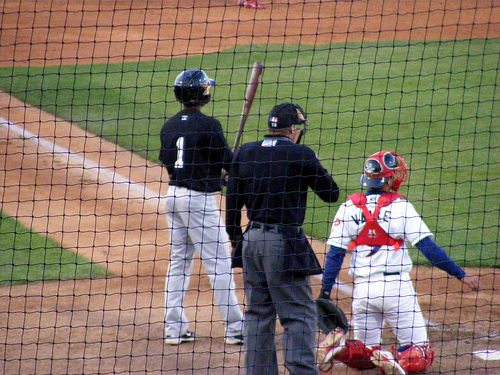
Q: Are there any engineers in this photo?
A: No, there are no engineers.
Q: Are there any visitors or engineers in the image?
A: No, there are no engineers or visitors.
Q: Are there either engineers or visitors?
A: No, there are no engineers or visitors.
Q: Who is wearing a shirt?
A: The man is wearing a shirt.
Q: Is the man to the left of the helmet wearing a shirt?
A: Yes, the man is wearing a shirt.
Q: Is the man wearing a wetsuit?
A: No, the man is wearing a shirt.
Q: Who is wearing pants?
A: The man is wearing pants.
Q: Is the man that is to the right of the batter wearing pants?
A: Yes, the man is wearing pants.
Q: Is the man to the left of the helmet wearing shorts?
A: No, the man is wearing pants.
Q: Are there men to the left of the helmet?
A: Yes, there is a man to the left of the helmet.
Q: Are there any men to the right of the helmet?
A: No, the man is to the left of the helmet.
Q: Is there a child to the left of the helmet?
A: No, there is a man to the left of the helmet.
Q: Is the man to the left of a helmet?
A: Yes, the man is to the left of a helmet.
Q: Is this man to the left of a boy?
A: No, the man is to the left of a helmet.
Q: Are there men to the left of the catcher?
A: Yes, there is a man to the left of the catcher.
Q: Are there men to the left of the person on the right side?
A: Yes, there is a man to the left of the catcher.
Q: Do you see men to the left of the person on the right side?
A: Yes, there is a man to the left of the catcher.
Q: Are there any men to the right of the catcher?
A: No, the man is to the left of the catcher.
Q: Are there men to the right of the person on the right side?
A: No, the man is to the left of the catcher.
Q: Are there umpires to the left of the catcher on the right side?
A: No, there is a man to the left of the catcher.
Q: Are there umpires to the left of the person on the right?
A: No, there is a man to the left of the catcher.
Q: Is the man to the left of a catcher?
A: Yes, the man is to the left of a catcher.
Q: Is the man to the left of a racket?
A: No, the man is to the left of a catcher.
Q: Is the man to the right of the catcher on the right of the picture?
A: No, the man is to the left of the catcher.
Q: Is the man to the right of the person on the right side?
A: No, the man is to the left of the catcher.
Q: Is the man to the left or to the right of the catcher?
A: The man is to the left of the catcher.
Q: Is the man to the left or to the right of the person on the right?
A: The man is to the left of the catcher.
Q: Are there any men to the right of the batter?
A: Yes, there is a man to the right of the batter.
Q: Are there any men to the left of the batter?
A: No, the man is to the right of the batter.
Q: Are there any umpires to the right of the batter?
A: No, there is a man to the right of the batter.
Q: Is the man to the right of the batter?
A: Yes, the man is to the right of the batter.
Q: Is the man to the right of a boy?
A: No, the man is to the right of the batter.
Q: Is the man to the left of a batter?
A: No, the man is to the right of a batter.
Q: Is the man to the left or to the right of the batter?
A: The man is to the right of the batter.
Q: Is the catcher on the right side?
A: Yes, the catcher is on the right of the image.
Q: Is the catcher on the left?
A: No, the catcher is on the right of the image.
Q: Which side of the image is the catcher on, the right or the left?
A: The catcher is on the right of the image.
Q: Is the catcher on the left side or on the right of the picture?
A: The catcher is on the right of the image.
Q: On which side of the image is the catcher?
A: The catcher is on the right of the image.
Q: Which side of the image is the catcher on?
A: The catcher is on the right of the image.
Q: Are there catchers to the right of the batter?
A: Yes, there is a catcher to the right of the batter.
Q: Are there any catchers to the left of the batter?
A: No, the catcher is to the right of the batter.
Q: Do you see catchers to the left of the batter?
A: No, the catcher is to the right of the batter.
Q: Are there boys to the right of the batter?
A: No, there is a catcher to the right of the batter.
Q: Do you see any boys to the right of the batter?
A: No, there is a catcher to the right of the batter.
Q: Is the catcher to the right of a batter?
A: Yes, the catcher is to the right of a batter.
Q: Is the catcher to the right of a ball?
A: No, the catcher is to the right of a batter.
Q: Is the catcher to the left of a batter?
A: No, the catcher is to the right of a batter.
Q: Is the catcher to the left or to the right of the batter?
A: The catcher is to the right of the batter.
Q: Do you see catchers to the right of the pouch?
A: Yes, there is a catcher to the right of the pouch.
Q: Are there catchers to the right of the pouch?
A: Yes, there is a catcher to the right of the pouch.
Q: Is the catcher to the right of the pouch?
A: Yes, the catcher is to the right of the pouch.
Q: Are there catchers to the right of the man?
A: Yes, there is a catcher to the right of the man.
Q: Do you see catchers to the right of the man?
A: Yes, there is a catcher to the right of the man.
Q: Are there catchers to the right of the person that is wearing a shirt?
A: Yes, there is a catcher to the right of the man.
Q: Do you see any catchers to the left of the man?
A: No, the catcher is to the right of the man.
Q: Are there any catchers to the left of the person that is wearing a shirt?
A: No, the catcher is to the right of the man.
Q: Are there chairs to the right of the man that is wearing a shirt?
A: No, there is a catcher to the right of the man.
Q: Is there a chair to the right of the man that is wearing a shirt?
A: No, there is a catcher to the right of the man.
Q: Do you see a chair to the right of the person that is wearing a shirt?
A: No, there is a catcher to the right of the man.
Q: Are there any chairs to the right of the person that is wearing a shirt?
A: No, there is a catcher to the right of the man.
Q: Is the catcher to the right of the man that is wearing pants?
A: Yes, the catcher is to the right of the man.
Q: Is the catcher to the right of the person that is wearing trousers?
A: Yes, the catcher is to the right of the man.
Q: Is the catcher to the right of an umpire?
A: No, the catcher is to the right of the man.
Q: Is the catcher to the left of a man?
A: No, the catcher is to the right of a man.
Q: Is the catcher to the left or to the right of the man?
A: The catcher is to the right of the man.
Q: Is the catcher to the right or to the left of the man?
A: The catcher is to the right of the man.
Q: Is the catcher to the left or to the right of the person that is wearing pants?
A: The catcher is to the right of the man.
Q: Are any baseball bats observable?
A: Yes, there is a baseball bat.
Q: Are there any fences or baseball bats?
A: Yes, there is a baseball bat.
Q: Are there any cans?
A: No, there are no cans.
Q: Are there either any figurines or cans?
A: No, there are no cans or figurines.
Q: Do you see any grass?
A: Yes, there is grass.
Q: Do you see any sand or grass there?
A: Yes, there is grass.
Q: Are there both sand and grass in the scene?
A: No, there is grass but no sand.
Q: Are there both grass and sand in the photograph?
A: No, there is grass but no sand.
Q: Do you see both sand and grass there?
A: No, there is grass but no sand.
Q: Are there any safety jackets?
A: No, there are no safety jackets.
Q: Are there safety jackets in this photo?
A: No, there are no safety jackets.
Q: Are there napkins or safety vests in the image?
A: No, there are no safety vests or napkins.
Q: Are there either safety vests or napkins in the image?
A: No, there are no safety vests or napkins.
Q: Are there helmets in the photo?
A: Yes, there is a helmet.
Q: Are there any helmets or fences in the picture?
A: Yes, there is a helmet.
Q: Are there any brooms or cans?
A: No, there are no cans or brooms.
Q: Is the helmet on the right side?
A: Yes, the helmet is on the right of the image.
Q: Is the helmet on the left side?
A: No, the helmet is on the right of the image.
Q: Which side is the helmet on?
A: The helmet is on the right of the image.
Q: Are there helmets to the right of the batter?
A: Yes, there is a helmet to the right of the batter.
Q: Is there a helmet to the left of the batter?
A: No, the helmet is to the right of the batter.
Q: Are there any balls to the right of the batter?
A: No, there is a helmet to the right of the batter.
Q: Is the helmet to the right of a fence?
A: No, the helmet is to the right of a batter.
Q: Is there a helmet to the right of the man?
A: Yes, there is a helmet to the right of the man.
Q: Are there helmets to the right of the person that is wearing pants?
A: Yes, there is a helmet to the right of the man.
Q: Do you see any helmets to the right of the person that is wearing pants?
A: Yes, there is a helmet to the right of the man.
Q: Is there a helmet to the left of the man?
A: No, the helmet is to the right of the man.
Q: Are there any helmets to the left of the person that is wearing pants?
A: No, the helmet is to the right of the man.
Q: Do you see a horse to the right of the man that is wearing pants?
A: No, there is a helmet to the right of the man.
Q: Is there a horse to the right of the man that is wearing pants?
A: No, there is a helmet to the right of the man.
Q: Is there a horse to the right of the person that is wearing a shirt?
A: No, there is a helmet to the right of the man.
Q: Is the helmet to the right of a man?
A: Yes, the helmet is to the right of a man.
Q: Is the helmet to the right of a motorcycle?
A: No, the helmet is to the right of a man.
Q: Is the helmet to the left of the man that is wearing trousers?
A: No, the helmet is to the right of the man.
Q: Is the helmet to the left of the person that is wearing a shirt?
A: No, the helmet is to the right of the man.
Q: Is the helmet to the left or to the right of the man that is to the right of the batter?
A: The helmet is to the right of the man.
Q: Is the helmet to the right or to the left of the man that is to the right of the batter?
A: The helmet is to the right of the man.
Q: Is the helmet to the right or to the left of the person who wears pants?
A: The helmet is to the right of the man.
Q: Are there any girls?
A: No, there are no girls.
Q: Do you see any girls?
A: No, there are no girls.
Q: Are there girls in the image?
A: No, there are no girls.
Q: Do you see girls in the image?
A: No, there are no girls.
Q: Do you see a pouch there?
A: Yes, there is a pouch.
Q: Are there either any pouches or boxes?
A: Yes, there is a pouch.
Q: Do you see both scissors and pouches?
A: No, there is a pouch but no scissors.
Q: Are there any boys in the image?
A: No, there are no boys.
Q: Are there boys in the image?
A: No, there are no boys.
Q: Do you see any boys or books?
A: No, there are no boys or books.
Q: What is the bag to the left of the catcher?
A: The bag is a pouch.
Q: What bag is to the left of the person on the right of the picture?
A: The bag is a pouch.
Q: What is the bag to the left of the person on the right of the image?
A: The bag is a pouch.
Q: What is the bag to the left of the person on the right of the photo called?
A: The bag is a pouch.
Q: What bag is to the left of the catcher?
A: The bag is a pouch.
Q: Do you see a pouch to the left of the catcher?
A: Yes, there is a pouch to the left of the catcher.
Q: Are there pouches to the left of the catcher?
A: Yes, there is a pouch to the left of the catcher.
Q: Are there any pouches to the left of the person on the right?
A: Yes, there is a pouch to the left of the catcher.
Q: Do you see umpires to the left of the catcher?
A: No, there is a pouch to the left of the catcher.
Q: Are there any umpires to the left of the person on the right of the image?
A: No, there is a pouch to the left of the catcher.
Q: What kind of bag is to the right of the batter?
A: The bag is a pouch.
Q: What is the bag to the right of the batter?
A: The bag is a pouch.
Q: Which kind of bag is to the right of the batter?
A: The bag is a pouch.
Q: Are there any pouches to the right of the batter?
A: Yes, there is a pouch to the right of the batter.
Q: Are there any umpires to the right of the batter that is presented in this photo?
A: No, there is a pouch to the right of the batter.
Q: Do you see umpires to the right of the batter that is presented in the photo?
A: No, there is a pouch to the right of the batter.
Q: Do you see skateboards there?
A: No, there are no skateboards.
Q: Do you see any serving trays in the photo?
A: No, there are no serving trays.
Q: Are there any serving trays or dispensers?
A: No, there are no serving trays or dispensers.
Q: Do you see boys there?
A: No, there are no boys.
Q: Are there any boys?
A: No, there are no boys.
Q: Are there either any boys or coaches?
A: No, there are no boys or coaches.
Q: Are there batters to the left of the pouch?
A: Yes, there is a batter to the left of the pouch.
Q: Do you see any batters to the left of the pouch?
A: Yes, there is a batter to the left of the pouch.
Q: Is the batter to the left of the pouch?
A: Yes, the batter is to the left of the pouch.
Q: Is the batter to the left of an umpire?
A: No, the batter is to the left of the pouch.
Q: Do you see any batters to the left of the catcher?
A: Yes, there is a batter to the left of the catcher.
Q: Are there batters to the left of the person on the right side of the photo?
A: Yes, there is a batter to the left of the catcher.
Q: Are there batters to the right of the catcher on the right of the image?
A: No, the batter is to the left of the catcher.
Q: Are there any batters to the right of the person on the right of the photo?
A: No, the batter is to the left of the catcher.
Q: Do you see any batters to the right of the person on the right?
A: No, the batter is to the left of the catcher.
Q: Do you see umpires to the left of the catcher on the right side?
A: No, there is a batter to the left of the catcher.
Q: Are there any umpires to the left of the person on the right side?
A: No, there is a batter to the left of the catcher.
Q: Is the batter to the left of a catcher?
A: Yes, the batter is to the left of a catcher.